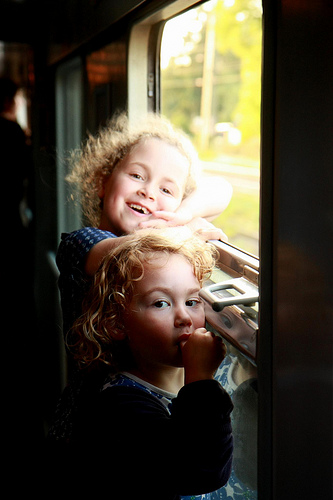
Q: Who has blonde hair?
A: Two girls.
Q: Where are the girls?
A: On a train.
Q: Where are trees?
A: Outside the window.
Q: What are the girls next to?
A: A window.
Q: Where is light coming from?
A: Window.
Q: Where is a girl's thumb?
A: In her mouth.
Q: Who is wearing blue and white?
A: Girl on the top.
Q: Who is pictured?
A: Two young girls.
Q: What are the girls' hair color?
A: Blonde.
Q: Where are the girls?
A: Inside a train.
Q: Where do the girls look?
A: Through a train window.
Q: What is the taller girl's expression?
A: Happiness and smiling.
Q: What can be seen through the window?
A: Day light.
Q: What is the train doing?
A: Moving.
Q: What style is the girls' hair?
A: Curly.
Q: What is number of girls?
A: Two.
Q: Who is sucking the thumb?
A: Small blonde child.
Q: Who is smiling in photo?
A: Tall girl.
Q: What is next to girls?
A: A window.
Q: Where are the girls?
A: Inside building.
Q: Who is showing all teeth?
A: Girl smiling.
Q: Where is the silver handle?
A: On window.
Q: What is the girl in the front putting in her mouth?
A: Her thumb.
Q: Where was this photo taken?
A: On a train.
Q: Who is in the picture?
A: Two young girls.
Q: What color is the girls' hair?
A: Blonde.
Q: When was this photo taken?
A: During the daytime.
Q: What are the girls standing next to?
A: The window.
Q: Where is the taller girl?
A: Behind the smaller girl.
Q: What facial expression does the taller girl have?
A: Smiling.